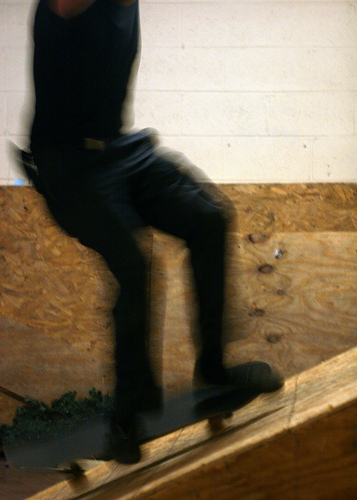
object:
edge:
[282, 346, 356, 383]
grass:
[3, 385, 107, 440]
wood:
[0, 186, 357, 419]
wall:
[0, 0, 357, 182]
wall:
[0, 183, 357, 428]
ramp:
[38, 342, 357, 499]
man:
[22, 2, 284, 465]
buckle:
[80, 135, 104, 152]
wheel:
[66, 474, 82, 490]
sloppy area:
[285, 349, 357, 453]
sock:
[198, 352, 222, 381]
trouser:
[34, 134, 111, 172]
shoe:
[192, 359, 284, 415]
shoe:
[109, 413, 142, 464]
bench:
[29, 344, 357, 498]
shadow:
[67, 384, 282, 498]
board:
[46, 341, 357, 498]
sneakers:
[191, 354, 280, 404]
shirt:
[28, 0, 144, 138]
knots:
[273, 247, 284, 259]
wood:
[231, 407, 357, 498]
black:
[64, 59, 97, 100]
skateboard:
[2, 373, 260, 480]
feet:
[192, 355, 285, 409]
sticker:
[9, 175, 25, 189]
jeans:
[32, 132, 233, 382]